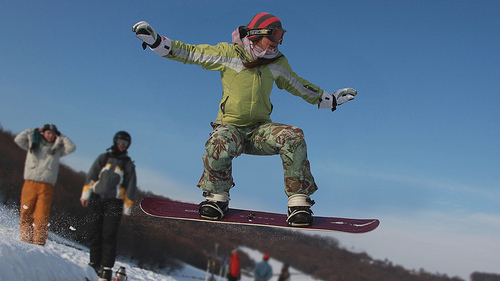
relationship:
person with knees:
[137, 12, 377, 233] [179, 122, 319, 173]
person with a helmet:
[137, 12, 377, 233] [222, 2, 293, 52]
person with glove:
[137, 12, 377, 233] [126, 20, 157, 48]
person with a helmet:
[107, 7, 436, 262] [239, 10, 291, 43]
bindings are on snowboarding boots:
[196, 199, 225, 214] [193, 189, 233, 218]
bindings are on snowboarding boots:
[283, 207, 312, 221] [281, 199, 320, 226]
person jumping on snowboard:
[137, 12, 377, 233] [137, 193, 382, 241]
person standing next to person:
[11, 123, 73, 247] [77, 130, 137, 279]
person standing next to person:
[77, 130, 137, 279] [11, 123, 73, 247]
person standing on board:
[137, 12, 377, 233] [137, 191, 381, 232]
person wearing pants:
[137, 12, 377, 233] [195, 119, 319, 197]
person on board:
[137, 12, 377, 233] [135, 197, 380, 232]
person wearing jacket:
[137, 12, 377, 233] [150, 24, 334, 127]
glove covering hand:
[126, 20, 157, 48] [130, 19, 158, 49]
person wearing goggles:
[137, 12, 377, 233] [244, 30, 282, 42]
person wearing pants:
[11, 123, 73, 247] [18, 177, 51, 247]